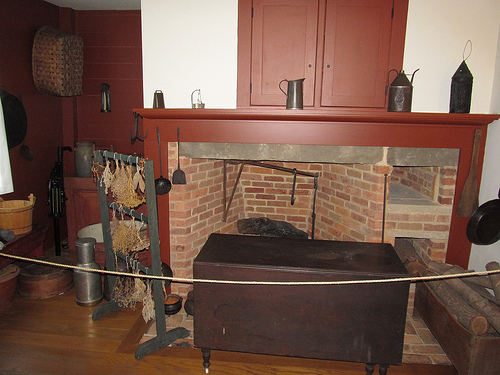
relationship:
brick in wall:
[141, 140, 455, 359] [228, 161, 312, 239]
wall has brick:
[213, 157, 340, 235] [253, 188, 278, 197]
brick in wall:
[141, 140, 455, 359] [172, 162, 446, 265]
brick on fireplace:
[141, 140, 455, 359] [164, 139, 463, 362]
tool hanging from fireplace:
[167, 122, 188, 185] [129, 104, 499, 308]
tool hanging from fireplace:
[148, 120, 169, 196] [129, 104, 499, 308]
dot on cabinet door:
[306, 58, 314, 71] [246, 0, 324, 111]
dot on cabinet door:
[323, 60, 335, 70] [246, 0, 324, 111]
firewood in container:
[421, 256, 499, 337] [412, 270, 499, 367]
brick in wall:
[339, 169, 364, 188] [171, 144, 451, 294]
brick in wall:
[141, 140, 455, 359] [172, 147, 448, 277]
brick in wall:
[141, 140, 455, 359] [164, 136, 419, 287]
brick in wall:
[141, 140, 455, 359] [175, 139, 461, 338]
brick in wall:
[141, 140, 455, 359] [166, 137, 433, 322]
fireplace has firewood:
[137, 80, 472, 322] [421, 256, 499, 337]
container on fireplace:
[277, 81, 321, 128] [171, 139, 434, 273]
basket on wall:
[34, 31, 86, 99] [81, 28, 143, 107]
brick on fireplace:
[141, 140, 455, 359] [144, 133, 394, 278]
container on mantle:
[277, 78, 304, 110] [132, 104, 499, 131]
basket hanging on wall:
[34, 31, 86, 99] [1, 2, 141, 226]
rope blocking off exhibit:
[1, 250, 498, 286] [1, 2, 499, 373]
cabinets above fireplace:
[235, 0, 411, 110] [130, 103, 499, 365]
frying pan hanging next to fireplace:
[464, 182, 499, 247] [130, 103, 499, 365]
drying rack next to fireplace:
[87, 144, 188, 357] [130, 103, 499, 365]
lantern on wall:
[94, 79, 115, 119] [76, 11, 142, 173]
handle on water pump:
[53, 145, 75, 174] [41, 142, 80, 261]